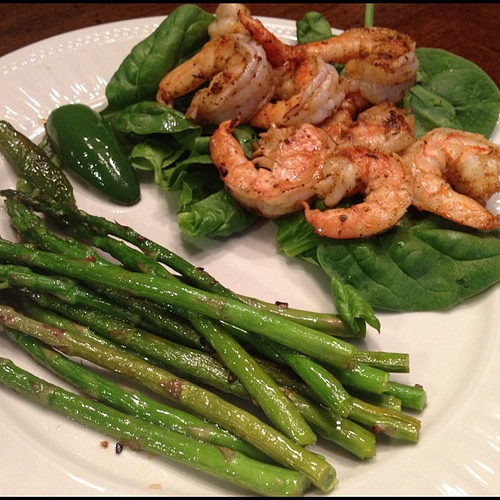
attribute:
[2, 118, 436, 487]
asparagus — roasted, baked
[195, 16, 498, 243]
shrimp — succulent, pink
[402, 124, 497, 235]
shrimp — pink, succulent, cooked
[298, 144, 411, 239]
shrimp — pink, cooked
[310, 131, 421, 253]
shrimp — pink, succulent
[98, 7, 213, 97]
leaf — green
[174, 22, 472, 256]
shrimp — fried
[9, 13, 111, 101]
plate — white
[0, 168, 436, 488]
asparagus — roasted, stacked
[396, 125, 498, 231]
shrimp — jumbo, sauteed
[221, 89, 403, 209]
shrimp — pink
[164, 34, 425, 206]
shrimp — sauteed, jumbo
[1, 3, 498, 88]
surface — wooden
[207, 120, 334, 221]
shrimp — cooked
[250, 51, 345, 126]
shrimp — cooked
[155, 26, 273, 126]
shrimp — cooked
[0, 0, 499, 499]
plate — round, white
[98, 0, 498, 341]
spinach — raw